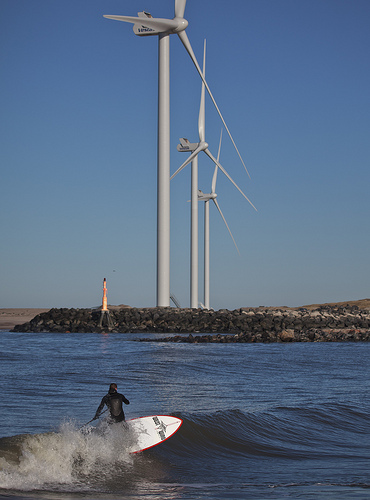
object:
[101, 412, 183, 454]
board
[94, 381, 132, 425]
surfer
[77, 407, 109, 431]
paddle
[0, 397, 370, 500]
wave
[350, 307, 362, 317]
rock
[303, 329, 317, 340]
rock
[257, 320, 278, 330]
rock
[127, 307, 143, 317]
rock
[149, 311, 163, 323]
rock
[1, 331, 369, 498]
water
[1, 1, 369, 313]
sky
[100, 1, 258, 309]
wind turbine